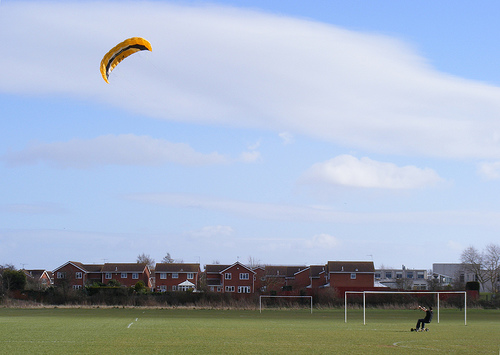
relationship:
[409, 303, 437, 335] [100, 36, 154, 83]
guy controlling kite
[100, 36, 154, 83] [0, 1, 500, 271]
kite in sky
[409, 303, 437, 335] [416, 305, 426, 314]
guy has arms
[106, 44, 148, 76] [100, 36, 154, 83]
stripe on kite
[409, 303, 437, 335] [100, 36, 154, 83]
guy holding kite